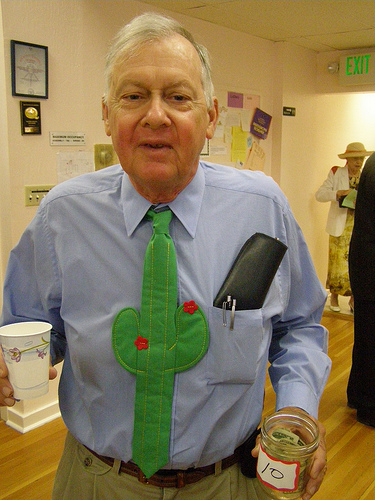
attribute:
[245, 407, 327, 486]
money —  jar.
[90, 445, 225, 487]
belt — brown.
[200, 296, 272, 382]
pocket —  shirt.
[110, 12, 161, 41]
hair — grey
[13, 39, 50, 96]
plaque — framed, silver, black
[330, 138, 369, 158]
hat — red, tan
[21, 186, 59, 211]
panel — yellow